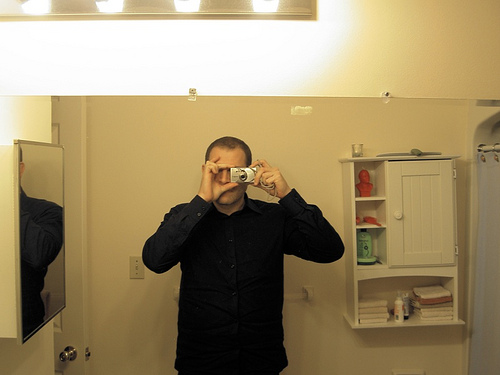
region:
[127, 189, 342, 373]
Solid black button up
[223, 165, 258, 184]
Small silver and grey camera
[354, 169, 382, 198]
Brick color statue head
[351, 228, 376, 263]
Green and black bottle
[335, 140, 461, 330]
White wall mounted cabinet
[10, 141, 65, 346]
Wall mounted mirror with reflection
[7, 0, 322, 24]
Row of light turned on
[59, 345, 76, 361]
Shiny silver door knob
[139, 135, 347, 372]
Guy holding a camera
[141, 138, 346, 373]
Guy wearing a button down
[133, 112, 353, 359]
man in long sleeve black shirt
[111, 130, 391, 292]
man taking a selfie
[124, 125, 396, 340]
man taking selfie with a camera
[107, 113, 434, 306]
man taking a selfie in the bathroom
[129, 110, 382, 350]
man using a mirror to take a selfie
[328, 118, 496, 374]
bathroom rack for toiletries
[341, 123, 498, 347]
washclothes next to shower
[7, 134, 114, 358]
medicine cabinent with mirror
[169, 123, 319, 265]
man using a grey camera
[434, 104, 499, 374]
blue shower curtain in shower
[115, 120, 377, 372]
a relection of a man in a large mirror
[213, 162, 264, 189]
a silver camera in a hand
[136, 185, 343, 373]
a black button up shirt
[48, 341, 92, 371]
a silver door knob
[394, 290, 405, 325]
a white bottle on a shelf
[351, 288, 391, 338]
a small stack of white towels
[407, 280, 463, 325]
a stack of towels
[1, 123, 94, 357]
a smaller mirror and cabinet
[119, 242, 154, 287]
a white light swich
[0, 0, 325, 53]
a row of lights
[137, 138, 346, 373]
person is taking selfie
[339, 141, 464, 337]
shelving is hung on wall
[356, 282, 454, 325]
washrags under door on shelf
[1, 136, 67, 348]
mirrored medicine cabinet on wall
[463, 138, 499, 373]
opaque shower curtain beside person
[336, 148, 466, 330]
bathroom shelf is painted white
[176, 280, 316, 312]
towel rack behind person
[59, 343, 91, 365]
metal doorknob handle on door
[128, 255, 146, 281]
lightswitch on wall behind person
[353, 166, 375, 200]
red bust on shelf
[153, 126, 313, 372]
this is a man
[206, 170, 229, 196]
the man is light skinned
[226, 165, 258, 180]
this is a camera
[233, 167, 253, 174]
the camera is white in color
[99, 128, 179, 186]
this is the wall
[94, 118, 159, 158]
the wall is white in color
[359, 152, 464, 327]
this is a cupboard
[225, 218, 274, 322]
this is a shirt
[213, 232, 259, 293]
the shirt is black in color